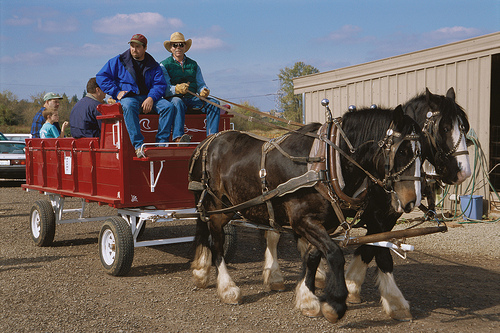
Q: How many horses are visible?
A: Two.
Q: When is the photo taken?
A: Daytime.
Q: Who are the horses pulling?
A: The people.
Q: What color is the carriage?
A: Red.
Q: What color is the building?
A: Brown.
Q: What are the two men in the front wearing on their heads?
A: Hats.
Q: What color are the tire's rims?
A: White.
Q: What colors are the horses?
A: Brown and White.